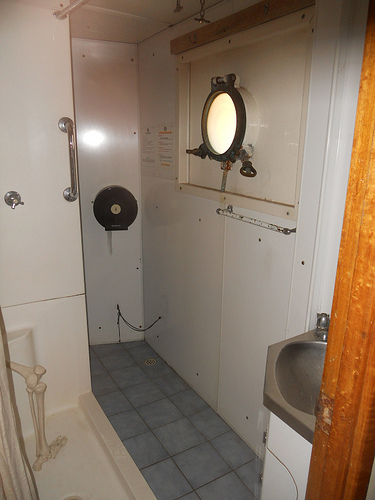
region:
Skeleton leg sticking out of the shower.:
[5, 357, 68, 470]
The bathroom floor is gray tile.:
[87, 339, 262, 496]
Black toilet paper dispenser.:
[93, 185, 138, 230]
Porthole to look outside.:
[201, 74, 246, 162]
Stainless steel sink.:
[264, 311, 324, 442]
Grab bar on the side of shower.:
[57, 116, 79, 201]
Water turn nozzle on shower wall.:
[4, 190, 24, 209]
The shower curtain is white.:
[0, 308, 39, 497]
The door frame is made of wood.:
[304, 0, 374, 499]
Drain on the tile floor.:
[144, 357, 155, 364]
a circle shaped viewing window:
[200, 74, 246, 160]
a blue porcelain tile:
[147, 416, 211, 456]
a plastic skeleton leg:
[9, 360, 67, 471]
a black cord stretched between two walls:
[116, 303, 164, 334]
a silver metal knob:
[316, 309, 329, 330]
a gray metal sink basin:
[264, 325, 338, 446]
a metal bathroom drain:
[144, 357, 157, 366]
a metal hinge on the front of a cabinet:
[260, 432, 267, 445]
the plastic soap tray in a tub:
[5, 330, 27, 345]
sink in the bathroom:
[268, 305, 360, 435]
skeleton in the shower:
[5, 335, 76, 493]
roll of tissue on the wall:
[83, 179, 145, 246]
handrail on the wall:
[50, 100, 80, 207]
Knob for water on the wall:
[6, 185, 30, 217]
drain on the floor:
[139, 353, 159, 370]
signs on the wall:
[137, 110, 177, 182]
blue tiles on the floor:
[100, 347, 234, 496]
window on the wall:
[184, 56, 265, 178]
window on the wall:
[188, 67, 272, 168]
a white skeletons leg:
[27, 386, 66, 474]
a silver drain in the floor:
[141, 351, 158, 376]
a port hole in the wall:
[196, 75, 252, 171]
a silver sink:
[260, 310, 326, 442]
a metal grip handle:
[57, 115, 83, 206]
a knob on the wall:
[5, 192, 24, 209]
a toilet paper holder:
[91, 183, 139, 234]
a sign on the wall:
[141, 118, 175, 182]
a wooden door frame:
[307, 182, 373, 496]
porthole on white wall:
[182, 70, 260, 183]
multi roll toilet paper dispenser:
[88, 181, 141, 258]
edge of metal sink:
[255, 310, 337, 498]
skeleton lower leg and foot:
[11, 353, 72, 474]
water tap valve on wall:
[3, 190, 27, 212]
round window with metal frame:
[179, 70, 263, 181]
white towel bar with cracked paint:
[210, 201, 297, 241]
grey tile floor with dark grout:
[123, 346, 179, 457]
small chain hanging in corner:
[113, 301, 165, 346]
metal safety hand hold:
[54, 113, 83, 206]